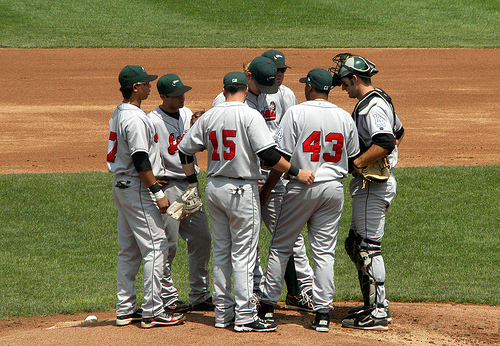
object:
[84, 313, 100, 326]
ball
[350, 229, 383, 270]
pad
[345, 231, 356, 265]
pad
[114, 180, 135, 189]
glove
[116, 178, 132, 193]
pocket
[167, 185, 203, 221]
glove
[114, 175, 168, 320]
pants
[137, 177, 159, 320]
line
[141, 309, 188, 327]
sneaker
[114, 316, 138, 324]
sneaker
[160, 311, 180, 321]
trim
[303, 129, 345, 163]
number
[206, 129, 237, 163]
number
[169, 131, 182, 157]
number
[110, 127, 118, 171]
number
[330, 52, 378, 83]
helmet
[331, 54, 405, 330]
player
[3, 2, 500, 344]
field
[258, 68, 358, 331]
player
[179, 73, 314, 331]
guy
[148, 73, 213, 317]
guy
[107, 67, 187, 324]
man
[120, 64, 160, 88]
cap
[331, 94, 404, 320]
uniform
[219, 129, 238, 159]
five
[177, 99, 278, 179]
jersey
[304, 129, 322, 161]
four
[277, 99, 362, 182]
jersey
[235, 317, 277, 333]
cleat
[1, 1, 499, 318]
grass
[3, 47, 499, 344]
dirt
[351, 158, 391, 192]
player's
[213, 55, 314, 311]
man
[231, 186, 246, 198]
glove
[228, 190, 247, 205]
pocket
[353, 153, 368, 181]
hand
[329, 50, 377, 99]
head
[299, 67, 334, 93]
cap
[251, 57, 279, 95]
cap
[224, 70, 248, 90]
cap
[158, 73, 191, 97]
cap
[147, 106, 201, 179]
jersey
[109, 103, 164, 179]
jersey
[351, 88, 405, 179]
jersey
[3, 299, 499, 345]
mound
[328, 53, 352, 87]
mask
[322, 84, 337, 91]
white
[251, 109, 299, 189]
arm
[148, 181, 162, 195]
band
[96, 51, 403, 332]
team